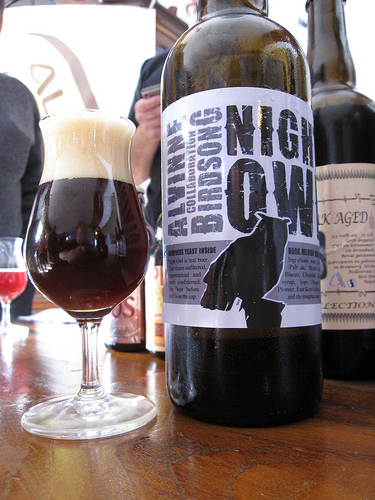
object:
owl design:
[199, 211, 293, 337]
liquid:
[0, 266, 27, 304]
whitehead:
[39, 114, 134, 184]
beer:
[159, 0, 322, 427]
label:
[312, 161, 374, 330]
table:
[0, 321, 374, 496]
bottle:
[160, 0, 322, 430]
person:
[128, 0, 239, 253]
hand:
[133, 96, 162, 140]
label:
[157, 90, 326, 332]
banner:
[1, 3, 162, 123]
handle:
[74, 320, 104, 393]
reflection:
[26, 180, 145, 274]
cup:
[19, 108, 157, 440]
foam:
[38, 113, 135, 188]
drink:
[0, 267, 28, 302]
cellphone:
[138, 80, 162, 99]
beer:
[22, 175, 147, 323]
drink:
[23, 113, 149, 324]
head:
[38, 115, 137, 187]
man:
[58, 210, 101, 260]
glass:
[17, 110, 156, 440]